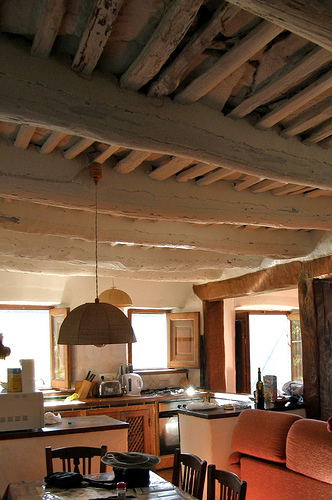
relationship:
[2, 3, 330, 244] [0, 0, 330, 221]
logs on ceiling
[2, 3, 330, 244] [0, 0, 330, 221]
logs in ceiling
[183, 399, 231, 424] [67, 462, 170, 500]
counter near table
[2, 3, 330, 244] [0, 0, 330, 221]
logs near ceiling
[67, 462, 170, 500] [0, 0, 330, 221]
table near ceiling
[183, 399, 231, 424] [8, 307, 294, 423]
counter in kitchen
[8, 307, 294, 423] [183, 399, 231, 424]
kitchen in counter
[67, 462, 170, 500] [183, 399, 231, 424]
table near counter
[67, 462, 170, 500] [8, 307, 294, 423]
table by kitchen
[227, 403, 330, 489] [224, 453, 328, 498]
cushions on seat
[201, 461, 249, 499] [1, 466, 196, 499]
chair next table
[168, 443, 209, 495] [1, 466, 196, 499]
chair next table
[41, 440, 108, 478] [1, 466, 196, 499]
chair next table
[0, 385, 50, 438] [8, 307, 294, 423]
microwave oven sitting on kitchen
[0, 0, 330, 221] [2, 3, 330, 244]
ceiling made of logs